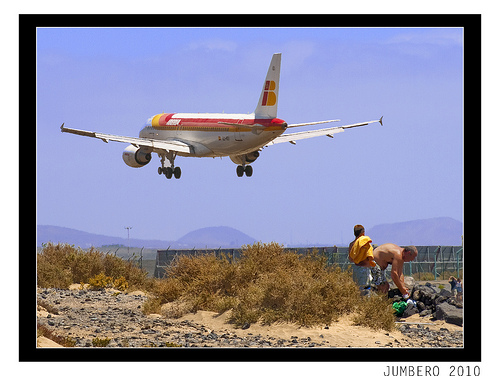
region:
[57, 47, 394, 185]
an airplane in flight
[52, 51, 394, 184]
an airplane with it's landing gear down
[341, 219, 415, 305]
two men standing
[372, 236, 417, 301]
a shirtless man bending over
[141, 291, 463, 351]
a sand dune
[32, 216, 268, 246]
mountains off in the distance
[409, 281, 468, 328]
black rocks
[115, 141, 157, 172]
an airplane's jet engine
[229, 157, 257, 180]
an airplane's landing gear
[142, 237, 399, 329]
brown green foliage growing in sand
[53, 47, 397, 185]
an airplane flying low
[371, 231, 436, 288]
a man with no shirt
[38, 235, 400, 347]
a grassy sandy area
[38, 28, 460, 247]
a blue sky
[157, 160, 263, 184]
landing gear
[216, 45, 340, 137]
a plane's tail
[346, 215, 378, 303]
a person holding a yellow shirt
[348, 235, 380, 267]
a yellow shirt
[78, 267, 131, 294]
a patch of yellow flowers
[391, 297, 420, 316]
a green piece of cloth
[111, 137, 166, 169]
an airplane engine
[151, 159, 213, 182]
landing gear on an airplane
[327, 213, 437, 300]
men at the beach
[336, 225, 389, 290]
man carrying a yellow towel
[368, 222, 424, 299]
a shirtless man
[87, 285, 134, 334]
rocks on a beach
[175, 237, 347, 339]
brown bushes in a sandy place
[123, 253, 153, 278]
metal chain link fence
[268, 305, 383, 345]
sand on a beach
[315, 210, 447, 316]
two men near rocks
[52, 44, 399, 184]
plane flying at low altitude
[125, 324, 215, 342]
grey rocks on the ground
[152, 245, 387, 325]
large patch of dry brown brush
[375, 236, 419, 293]
man not wearing a shirt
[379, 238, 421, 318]
man bending towards the ground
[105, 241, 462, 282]
tall fence in the distance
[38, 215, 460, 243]
low blue hills in the distance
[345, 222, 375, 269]
person with yellow cloth object on right shoulder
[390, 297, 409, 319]
green object on the ground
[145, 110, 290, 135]
orange and red paint on plane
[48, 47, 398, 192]
a large airplane taking off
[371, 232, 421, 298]
a older man with no shirt on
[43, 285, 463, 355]
rocks all over the ground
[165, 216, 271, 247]
a mountain in the distance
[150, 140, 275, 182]
wheels under a plane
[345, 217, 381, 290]
a boy holding a yellow towel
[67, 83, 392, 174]
a white with yellow and red stripes colored plane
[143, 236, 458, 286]
a long line of solar panels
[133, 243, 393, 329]
dried out weeds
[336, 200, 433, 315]
two people outside